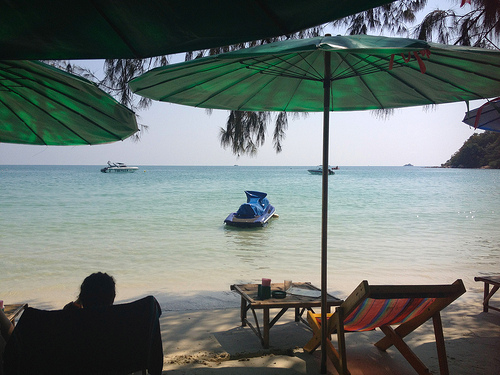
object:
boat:
[100, 160, 140, 173]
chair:
[292, 277, 467, 374]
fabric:
[341, 298, 439, 332]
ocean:
[0, 164, 500, 282]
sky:
[0, 0, 500, 164]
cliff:
[438, 101, 500, 168]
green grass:
[162, 350, 233, 364]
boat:
[224, 190, 279, 227]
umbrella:
[1, 61, 138, 147]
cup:
[257, 283, 272, 300]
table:
[229, 278, 344, 350]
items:
[271, 290, 287, 298]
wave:
[32, 188, 195, 257]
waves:
[342, 164, 497, 244]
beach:
[0, 289, 498, 374]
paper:
[285, 286, 321, 298]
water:
[3, 160, 498, 295]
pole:
[317, 76, 334, 374]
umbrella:
[124, 32, 499, 115]